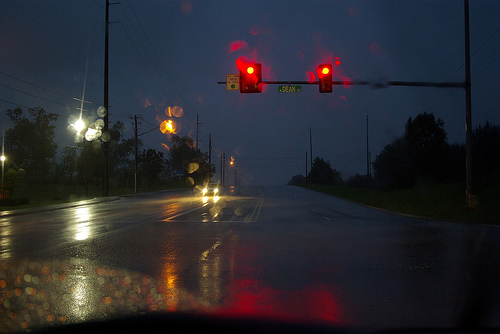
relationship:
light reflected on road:
[61, 194, 109, 248] [2, 183, 488, 332]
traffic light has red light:
[316, 53, 334, 93] [316, 64, 334, 77]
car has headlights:
[199, 180, 229, 196] [200, 185, 220, 195]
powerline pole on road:
[99, 0, 113, 192] [110, 200, 162, 236]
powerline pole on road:
[130, 113, 142, 187] [132, 211, 137, 221]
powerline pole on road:
[364, 115, 374, 195] [284, 230, 296, 246]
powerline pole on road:
[306, 126, 316, 173] [259, 213, 271, 225]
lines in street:
[254, 200, 264, 225] [268, 217, 288, 244]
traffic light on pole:
[232, 51, 268, 94] [459, 2, 477, 131]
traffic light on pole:
[316, 48, 334, 93] [459, 2, 477, 131]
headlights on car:
[197, 184, 222, 194] [199, 180, 229, 196]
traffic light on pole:
[316, 48, 334, 93] [464, 0, 474, 147]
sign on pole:
[221, 71, 241, 92] [461, 10, 479, 124]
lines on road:
[254, 200, 264, 225] [266, 253, 271, 258]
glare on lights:
[87, 115, 104, 140] [70, 120, 84, 130]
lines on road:
[245, 196, 265, 224] [0, 183, 416, 321]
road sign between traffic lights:
[276, 85, 303, 95] [233, 58, 335, 96]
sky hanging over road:
[2, 3, 483, 185] [2, 183, 488, 332]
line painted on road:
[322, 216, 331, 222] [0, 184, 500, 333]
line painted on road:
[308, 208, 318, 215] [0, 184, 500, 333]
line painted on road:
[301, 199, 309, 207] [0, 184, 500, 333]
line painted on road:
[301, 199, 309, 209] [0, 184, 500, 333]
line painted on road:
[288, 191, 291, 194] [0, 184, 500, 333]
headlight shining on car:
[202, 186, 209, 193] [201, 180, 221, 197]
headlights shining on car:
[209, 184, 222, 194] [201, 180, 221, 197]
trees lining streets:
[289, 112, 493, 209] [0, 182, 490, 325]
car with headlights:
[199, 180, 220, 196] [209, 184, 222, 194]